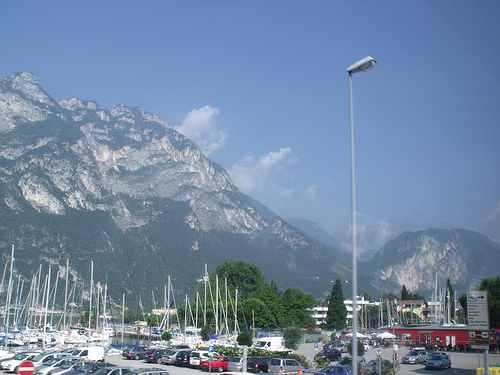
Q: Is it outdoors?
A: Yes, it is outdoors.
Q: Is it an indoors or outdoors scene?
A: It is outdoors.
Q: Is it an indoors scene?
A: No, it is outdoors.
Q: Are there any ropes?
A: No, there are no ropes.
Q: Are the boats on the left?
A: Yes, the boats are on the left of the image.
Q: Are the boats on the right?
A: No, the boats are on the left of the image.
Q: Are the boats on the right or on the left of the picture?
A: The boats are on the left of the image.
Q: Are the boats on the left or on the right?
A: The boats are on the left of the image.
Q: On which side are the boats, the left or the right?
A: The boats are on the left of the image.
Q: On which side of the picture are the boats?
A: The boats are on the left of the image.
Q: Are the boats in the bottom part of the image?
A: Yes, the boats are in the bottom of the image.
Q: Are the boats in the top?
A: No, the boats are in the bottom of the image.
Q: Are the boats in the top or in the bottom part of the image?
A: The boats are in the bottom of the image.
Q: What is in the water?
A: The boats are in the water.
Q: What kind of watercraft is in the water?
A: The watercraft is boats.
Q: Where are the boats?
A: The boats are in the water.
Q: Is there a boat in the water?
A: Yes, there are boats in the water.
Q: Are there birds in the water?
A: No, there are boats in the water.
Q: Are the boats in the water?
A: Yes, the boats are in the water.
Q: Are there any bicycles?
A: No, there are no bicycles.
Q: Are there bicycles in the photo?
A: No, there are no bicycles.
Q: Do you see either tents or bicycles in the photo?
A: No, there are no bicycles or tents.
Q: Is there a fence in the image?
A: No, there are no fences.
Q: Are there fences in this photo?
A: No, there are no fences.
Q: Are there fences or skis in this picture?
A: No, there are no fences or skis.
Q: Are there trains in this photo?
A: No, there are no trains.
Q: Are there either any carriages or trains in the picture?
A: No, there are no trains or carriages.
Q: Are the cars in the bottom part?
A: Yes, the cars are in the bottom of the image.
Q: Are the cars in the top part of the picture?
A: No, the cars are in the bottom of the image.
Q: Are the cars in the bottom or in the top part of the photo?
A: The cars are in the bottom of the image.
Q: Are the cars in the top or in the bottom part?
A: The cars are in the bottom of the image.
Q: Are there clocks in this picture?
A: No, there are no clocks.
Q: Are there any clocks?
A: No, there are no clocks.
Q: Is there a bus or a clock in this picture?
A: No, there are no clocks or buses.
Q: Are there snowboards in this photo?
A: No, there are no snowboards.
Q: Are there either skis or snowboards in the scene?
A: No, there are no snowboards or skis.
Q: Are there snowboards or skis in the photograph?
A: No, there are no snowboards or skis.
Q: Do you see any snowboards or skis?
A: No, there are no snowboards or skis.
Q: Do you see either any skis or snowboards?
A: No, there are no snowboards or skis.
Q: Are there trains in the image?
A: No, there are no trains.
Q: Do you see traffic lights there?
A: No, there are no traffic lights.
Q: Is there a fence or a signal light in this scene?
A: No, there are no traffic lights or fences.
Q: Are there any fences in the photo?
A: No, there are no fences.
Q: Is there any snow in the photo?
A: Yes, there is snow.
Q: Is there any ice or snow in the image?
A: Yes, there is snow.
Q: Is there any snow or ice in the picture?
A: Yes, there is snow.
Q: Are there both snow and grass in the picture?
A: No, there is snow but no grass.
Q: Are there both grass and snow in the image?
A: No, there is snow but no grass.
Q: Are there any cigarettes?
A: No, there are no cigarettes.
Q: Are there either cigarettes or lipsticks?
A: No, there are no cigarettes or lipsticks.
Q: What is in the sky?
A: The clouds are in the sky.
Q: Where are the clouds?
A: The clouds are in the sky.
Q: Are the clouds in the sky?
A: Yes, the clouds are in the sky.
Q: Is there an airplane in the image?
A: No, there are no airplanes.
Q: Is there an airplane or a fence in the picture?
A: No, there are no airplanes or fences.